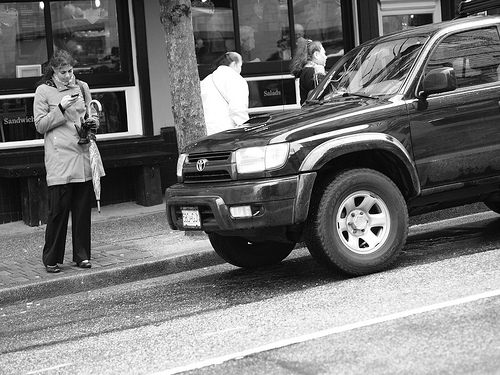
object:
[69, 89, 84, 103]
cell phone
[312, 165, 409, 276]
tire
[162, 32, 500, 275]
car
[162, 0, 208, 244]
tree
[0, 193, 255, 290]
sidewalk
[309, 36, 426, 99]
windshield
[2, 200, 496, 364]
road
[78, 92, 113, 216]
umbrella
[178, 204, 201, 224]
license plate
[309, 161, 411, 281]
wheels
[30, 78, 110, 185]
coat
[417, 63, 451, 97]
mirror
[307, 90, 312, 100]
mirror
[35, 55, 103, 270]
woman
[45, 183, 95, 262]
pants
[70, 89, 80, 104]
smartphone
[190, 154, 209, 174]
logo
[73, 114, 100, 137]
hand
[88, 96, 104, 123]
handle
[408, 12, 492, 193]
side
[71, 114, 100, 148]
glove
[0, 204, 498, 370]
street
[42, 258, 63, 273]
shoes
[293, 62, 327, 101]
coat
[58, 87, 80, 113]
hand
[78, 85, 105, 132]
woman's arm